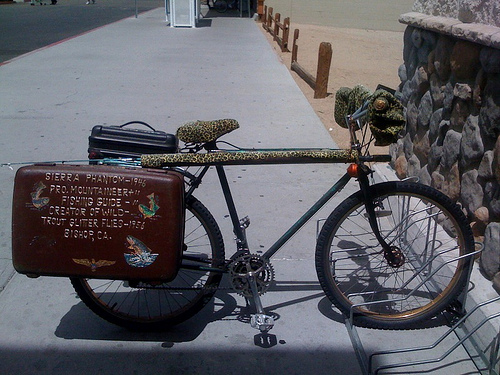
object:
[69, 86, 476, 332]
bicycle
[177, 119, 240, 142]
seat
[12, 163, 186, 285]
suitcase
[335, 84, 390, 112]
handlebars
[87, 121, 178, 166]
case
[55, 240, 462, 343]
shadow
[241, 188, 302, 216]
pavement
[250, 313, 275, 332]
pedal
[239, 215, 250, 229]
pedal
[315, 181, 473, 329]
tire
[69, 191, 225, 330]
tire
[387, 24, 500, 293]
rock wall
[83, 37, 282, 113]
sidewalk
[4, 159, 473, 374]
right side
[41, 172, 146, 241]
words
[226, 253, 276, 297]
gears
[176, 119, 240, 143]
design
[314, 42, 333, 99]
pole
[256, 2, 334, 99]
fence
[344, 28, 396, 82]
beach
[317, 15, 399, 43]
sand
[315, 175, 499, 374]
bike rack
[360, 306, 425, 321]
rim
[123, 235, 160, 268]
stickers